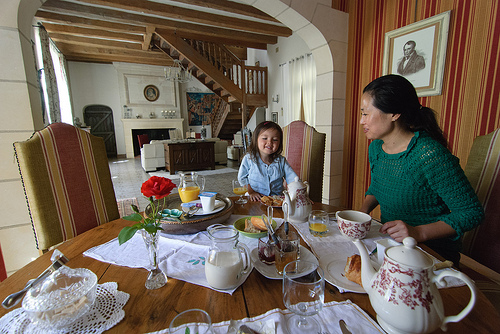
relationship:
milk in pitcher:
[209, 259, 237, 285] [200, 221, 257, 294]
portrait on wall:
[372, 17, 454, 101] [340, 18, 380, 112]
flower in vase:
[129, 180, 169, 230] [139, 226, 174, 298]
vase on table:
[139, 226, 174, 298] [66, 229, 161, 318]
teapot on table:
[275, 177, 312, 231] [66, 229, 161, 318]